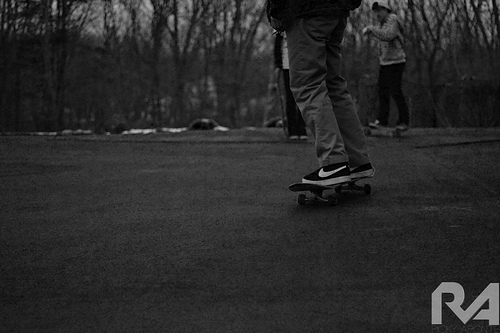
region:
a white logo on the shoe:
[293, 160, 370, 192]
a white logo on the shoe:
[263, 144, 380, 199]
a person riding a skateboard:
[266, 15, 382, 255]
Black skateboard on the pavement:
[283, 162, 393, 213]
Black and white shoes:
[269, 139, 437, 229]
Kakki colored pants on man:
[250, 8, 390, 178]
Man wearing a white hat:
[369, 1, 402, 13]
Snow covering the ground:
[123, 115, 234, 145]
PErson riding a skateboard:
[367, 49, 446, 169]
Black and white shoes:
[363, 114, 414, 138]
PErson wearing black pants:
[369, 56, 429, 152]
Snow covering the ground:
[34, 99, 279, 138]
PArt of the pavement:
[24, 195, 253, 306]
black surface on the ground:
[77, 202, 218, 282]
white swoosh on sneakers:
[303, 157, 353, 180]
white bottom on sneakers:
[329, 176, 351, 189]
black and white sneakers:
[293, 153, 360, 187]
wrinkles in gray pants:
[285, 60, 327, 102]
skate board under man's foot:
[281, 172, 386, 207]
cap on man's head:
[371, 2, 401, 14]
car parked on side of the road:
[185, 108, 229, 140]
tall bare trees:
[38, 14, 170, 130]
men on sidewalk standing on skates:
[245, 4, 417, 204]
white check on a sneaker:
[310, 164, 346, 181]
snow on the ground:
[71, 125, 188, 136]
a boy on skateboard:
[361, 4, 410, 129]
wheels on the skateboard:
[299, 188, 341, 203]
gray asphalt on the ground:
[36, 142, 266, 316]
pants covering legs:
[285, 20, 367, 162]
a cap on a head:
[370, 1, 392, 10]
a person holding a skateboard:
[271, 30, 295, 138]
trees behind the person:
[18, 2, 242, 119]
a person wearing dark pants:
[369, 2, 426, 139]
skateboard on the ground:
[279, 152, 413, 222]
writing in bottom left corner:
[410, 270, 499, 330]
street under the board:
[171, 183, 262, 258]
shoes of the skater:
[292, 147, 384, 200]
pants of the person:
[273, 15, 386, 186]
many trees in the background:
[75, 15, 248, 87]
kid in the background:
[351, 0, 427, 70]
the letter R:
[420, 265, 471, 330]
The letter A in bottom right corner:
[463, 275, 498, 325]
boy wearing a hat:
[364, 0, 395, 21]